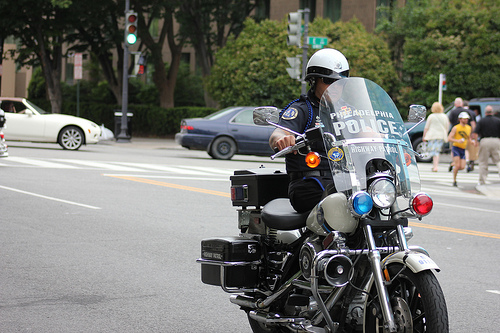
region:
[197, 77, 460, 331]
the motorcycle on the street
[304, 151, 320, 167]
the orange light on the motorcycle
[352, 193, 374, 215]
the blue light on the motorcycle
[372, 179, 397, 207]
the white light on the motorcycle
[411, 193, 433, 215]
the red light on the motorcycle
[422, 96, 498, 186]
the people on the sidewalk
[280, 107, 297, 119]
the patch on the man's uniform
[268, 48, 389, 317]
the man dressed in the police uniform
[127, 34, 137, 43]
the green traffic light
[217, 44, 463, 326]
police motorcycle on road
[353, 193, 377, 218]
light on the bike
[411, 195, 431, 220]
light on the bike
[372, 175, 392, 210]
light on the bike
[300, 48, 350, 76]
helmet on the bike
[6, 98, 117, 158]
car on the road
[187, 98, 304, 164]
car on the road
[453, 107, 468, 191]
person on the road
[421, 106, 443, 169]
person on the road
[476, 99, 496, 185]
person on the road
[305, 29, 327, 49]
green and white street sign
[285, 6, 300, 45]
traffic signal on pole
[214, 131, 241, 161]
rear black tire on blue car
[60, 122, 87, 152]
front passenger side tire on white car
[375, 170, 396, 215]
head light on police bike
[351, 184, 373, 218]
blue light on front of bike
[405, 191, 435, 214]
red light on front of bike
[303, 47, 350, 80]
white and black helmet on man's head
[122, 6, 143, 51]
green light on traffic signal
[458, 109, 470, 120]
white hat on person's head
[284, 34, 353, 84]
The helmet is white.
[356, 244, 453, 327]
The tire is black.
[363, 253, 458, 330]
The tire is rubber.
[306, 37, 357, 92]
The man is wearing a helmet.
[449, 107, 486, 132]
The man is wearing a hat.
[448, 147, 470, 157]
The mans shorts are blue.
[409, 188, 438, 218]
The light is red.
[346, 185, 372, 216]
The light is blue.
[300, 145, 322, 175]
The light is orange.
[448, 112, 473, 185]
a man in a yellow shirt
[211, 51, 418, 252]
a police officer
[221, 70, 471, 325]
a police officer on a motorcycle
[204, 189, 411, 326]
a black and white motorcycle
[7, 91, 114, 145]
a white car on the street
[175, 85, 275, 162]
a blue car on the street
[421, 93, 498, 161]
people waiting to cross the street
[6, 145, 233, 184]
the crosswalk on the road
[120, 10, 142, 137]
a tall street light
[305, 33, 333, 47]
a green street sign